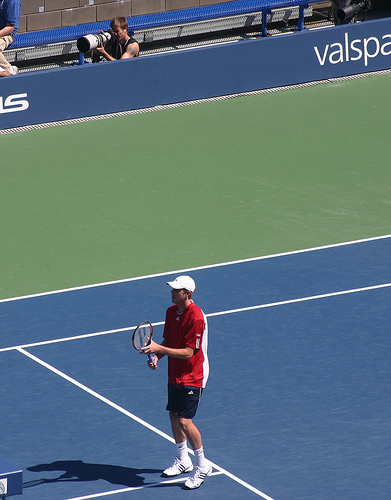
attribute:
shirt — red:
[160, 300, 211, 387]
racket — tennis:
[130, 318, 157, 368]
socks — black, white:
[192, 446, 204, 463]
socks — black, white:
[173, 440, 186, 458]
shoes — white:
[161, 459, 212, 489]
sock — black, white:
[192, 446, 205, 465]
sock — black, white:
[176, 440, 187, 462]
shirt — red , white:
[162, 298, 207, 387]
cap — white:
[164, 276, 196, 289]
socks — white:
[143, 430, 234, 467]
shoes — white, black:
[162, 458, 194, 474]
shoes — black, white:
[184, 456, 211, 487]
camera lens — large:
[77, 30, 114, 54]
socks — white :
[166, 435, 214, 473]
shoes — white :
[161, 456, 213, 491]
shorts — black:
[162, 377, 206, 421]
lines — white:
[112, 44, 336, 366]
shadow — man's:
[24, 459, 187, 489]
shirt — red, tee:
[131, 262, 220, 392]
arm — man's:
[122, 320, 203, 360]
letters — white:
[315, 19, 358, 74]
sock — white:
[192, 445, 208, 466]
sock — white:
[174, 440, 188, 458]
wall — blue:
[85, 33, 378, 114]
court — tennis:
[5, 474, 378, 494]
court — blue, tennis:
[3, 194, 378, 496]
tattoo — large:
[164, 346, 190, 362]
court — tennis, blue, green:
[4, 108, 375, 495]